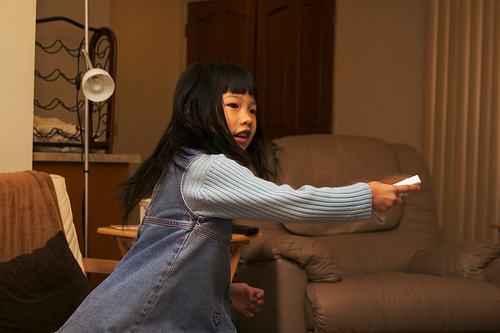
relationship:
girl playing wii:
[53, 59, 421, 331] [371, 172, 421, 226]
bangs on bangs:
[217, 63, 260, 98] [217, 63, 260, 98]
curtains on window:
[425, 0, 499, 246] [420, 0, 498, 245]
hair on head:
[107, 59, 285, 231] [172, 62, 257, 153]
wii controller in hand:
[371, 172, 421, 226] [364, 180, 422, 214]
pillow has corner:
[2, 230, 91, 332] [48, 229, 70, 244]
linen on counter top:
[33, 113, 101, 154] [31, 153, 145, 163]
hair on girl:
[107, 59, 285, 231] [53, 59, 421, 331]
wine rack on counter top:
[35, 16, 118, 153] [31, 153, 145, 163]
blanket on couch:
[0, 169, 66, 264] [2, 170, 121, 332]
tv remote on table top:
[231, 221, 261, 238] [98, 223, 264, 243]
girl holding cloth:
[53, 59, 421, 331] [370, 175, 421, 225]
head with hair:
[172, 62, 257, 153] [107, 59, 285, 231]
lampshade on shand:
[82, 68, 116, 102] [83, 2, 89, 256]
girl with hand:
[53, 59, 421, 331] [364, 180, 422, 214]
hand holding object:
[364, 180, 422, 214] [371, 172, 421, 226]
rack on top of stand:
[35, 16, 118, 153] [31, 153, 145, 163]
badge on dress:
[212, 310, 221, 323] [54, 146, 240, 331]